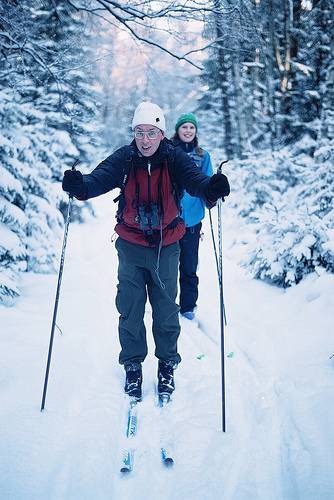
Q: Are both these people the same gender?
A: No, they are both male and female.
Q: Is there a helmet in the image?
A: No, there are no helmets.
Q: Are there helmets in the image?
A: No, there are no helmets.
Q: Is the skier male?
A: Yes, the skier is male.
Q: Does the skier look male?
A: Yes, the skier is male.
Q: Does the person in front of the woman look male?
A: Yes, the skier is male.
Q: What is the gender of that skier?
A: The skier is male.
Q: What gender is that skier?
A: The skier is male.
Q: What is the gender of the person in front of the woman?
A: The skier is male.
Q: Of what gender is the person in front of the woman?
A: The skier is male.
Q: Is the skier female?
A: No, the skier is male.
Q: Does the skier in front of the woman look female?
A: No, the skier is male.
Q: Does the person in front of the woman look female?
A: No, the skier is male.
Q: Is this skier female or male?
A: The skier is male.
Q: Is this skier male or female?
A: The skier is male.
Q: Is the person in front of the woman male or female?
A: The skier is male.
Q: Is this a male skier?
A: Yes, this is a male skier.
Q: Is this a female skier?
A: No, this is a male skier.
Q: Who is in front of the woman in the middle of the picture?
A: The skier is in front of the woman.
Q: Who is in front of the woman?
A: The skier is in front of the woman.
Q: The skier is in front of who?
A: The skier is in front of the woman.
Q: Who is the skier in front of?
A: The skier is in front of the woman.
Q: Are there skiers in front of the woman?
A: Yes, there is a skier in front of the woman.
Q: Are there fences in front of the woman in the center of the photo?
A: No, there is a skier in front of the woman.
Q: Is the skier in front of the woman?
A: Yes, the skier is in front of the woman.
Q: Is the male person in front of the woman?
A: Yes, the skier is in front of the woman.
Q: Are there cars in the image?
A: No, there are no cars.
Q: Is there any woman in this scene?
A: Yes, there is a woman.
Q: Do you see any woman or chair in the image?
A: Yes, there is a woman.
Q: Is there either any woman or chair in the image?
A: Yes, there is a woman.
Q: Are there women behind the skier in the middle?
A: Yes, there is a woman behind the skier.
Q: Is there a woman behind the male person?
A: Yes, there is a woman behind the skier.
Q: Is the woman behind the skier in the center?
A: Yes, the woman is behind the skier.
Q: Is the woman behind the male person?
A: Yes, the woman is behind the skier.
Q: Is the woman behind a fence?
A: No, the woman is behind the skier.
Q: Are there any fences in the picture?
A: No, there are no fences.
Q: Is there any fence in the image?
A: No, there are no fences.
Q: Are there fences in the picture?
A: No, there are no fences.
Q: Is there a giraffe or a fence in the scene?
A: No, there are no fences or giraffes.